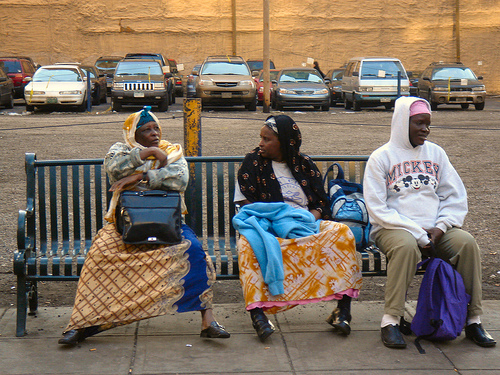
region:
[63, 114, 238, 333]
lady on bench in skirt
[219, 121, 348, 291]
blue shweatshirt on lap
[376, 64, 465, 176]
pink hat on head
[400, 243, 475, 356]
purple and black backpack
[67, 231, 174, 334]
brown checked print skirt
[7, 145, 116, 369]
dark bench on sidewalk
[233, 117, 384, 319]
orange and white skirt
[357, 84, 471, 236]
white sweatshirt with pink and black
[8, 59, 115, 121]
car parked in space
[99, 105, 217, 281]
black bag on lap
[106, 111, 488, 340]
three people sitting on bench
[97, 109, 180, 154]
woman wears yellow hood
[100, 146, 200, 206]
woman wears grey jacket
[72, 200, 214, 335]
woman wears brown checked dress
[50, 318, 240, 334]
woman wears black shoes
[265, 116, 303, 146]
woman wears black hood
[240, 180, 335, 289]
woman has blue shirt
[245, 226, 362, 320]
woman wears orange dress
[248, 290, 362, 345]
woman wears black shoes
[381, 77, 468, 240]
man wears grey hoodie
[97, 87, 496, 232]
three women sitting on a bench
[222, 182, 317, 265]
a blue sweater on a woman's lap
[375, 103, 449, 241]
a woman wearing a white mickey mouse sweater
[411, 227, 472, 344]
a purple backpack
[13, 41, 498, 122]
a row of parked cars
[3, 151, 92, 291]
a black metal bench on a sidewalk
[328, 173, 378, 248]
a blue backpack between two women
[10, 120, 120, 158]
a large dirt lot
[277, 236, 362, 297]
an orange and white skirt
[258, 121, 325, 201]
a black shawl on a woman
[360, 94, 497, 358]
woman sitting on the right side of the bench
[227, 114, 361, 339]
woman sitting in the middle of the bench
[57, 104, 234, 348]
woman sitting on the left side of the bench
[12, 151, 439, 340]
green, metal bench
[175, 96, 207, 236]
yellow painted pole behind the bench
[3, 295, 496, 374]
grey sidewalk with dirt on it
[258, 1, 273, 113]
brown pole in the parking lot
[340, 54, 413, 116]
white van in the parking lot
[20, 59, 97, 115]
white car in the parking lot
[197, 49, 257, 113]
brown suv in the parking lot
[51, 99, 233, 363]
The woman is sitting.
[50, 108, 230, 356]
The woman has her legs spread open.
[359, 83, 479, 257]
Mickey Mouse on a hoodie.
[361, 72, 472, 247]
The hoodie is white.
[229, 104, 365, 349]
The woman is sitting.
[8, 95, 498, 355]
Three people on a bench.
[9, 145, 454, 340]
The bench is green.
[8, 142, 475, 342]
The bench is metal.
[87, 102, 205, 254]
The woman is holding a black purse.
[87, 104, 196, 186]
The woman has her head covered.